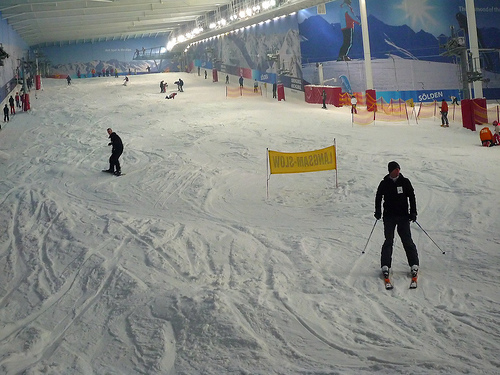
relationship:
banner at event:
[267, 138, 338, 200] [5, 5, 495, 373]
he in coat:
[361, 161, 446, 290] [374, 173, 418, 216]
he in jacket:
[102, 128, 126, 177] [107, 129, 126, 159]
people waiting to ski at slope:
[46, 61, 180, 90] [11, 73, 491, 373]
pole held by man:
[415, 220, 447, 255] [370, 152, 440, 310]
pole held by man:
[360, 213, 389, 270] [371, 157, 444, 316]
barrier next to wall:
[301, 79, 353, 114] [163, 3, 496, 137]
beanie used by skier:
[383, 155, 416, 182] [363, 157, 434, 281]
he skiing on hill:
[361, 161, 446, 290] [12, 68, 492, 373]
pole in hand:
[415, 216, 463, 264] [408, 203, 421, 222]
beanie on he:
[388, 161, 401, 174] [361, 161, 446, 290]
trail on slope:
[7, 178, 277, 368] [11, 73, 491, 373]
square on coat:
[395, 182, 410, 201] [370, 174, 421, 224]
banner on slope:
[265, 142, 352, 194] [11, 73, 491, 373]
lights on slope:
[157, 0, 296, 53] [11, 73, 491, 373]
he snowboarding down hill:
[102, 128, 126, 177] [12, 68, 492, 373]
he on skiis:
[361, 161, 446, 290] [368, 254, 436, 304]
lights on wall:
[157, 0, 296, 53] [200, 19, 335, 100]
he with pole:
[361, 161, 446, 290] [361, 219, 378, 254]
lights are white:
[165, 24, 205, 50] [266, 207, 319, 242]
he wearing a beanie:
[361, 161, 446, 290] [388, 161, 401, 174]